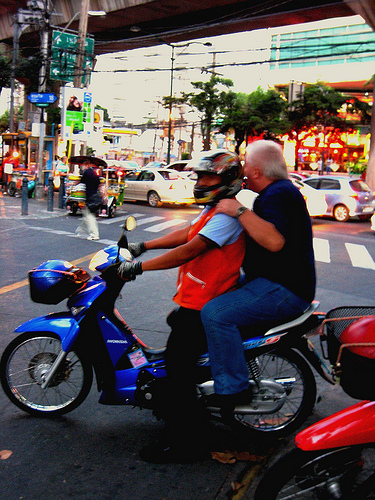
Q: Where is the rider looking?
A: To the left.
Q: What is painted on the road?
A: White stripes.